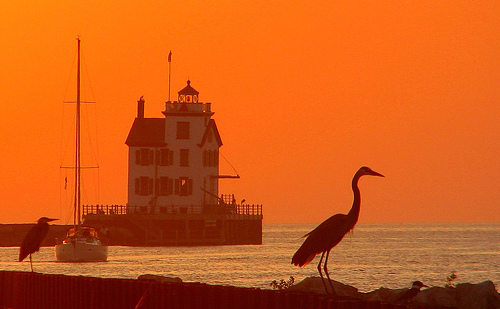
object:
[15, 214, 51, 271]
bird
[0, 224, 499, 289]
water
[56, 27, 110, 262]
boat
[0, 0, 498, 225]
orange sky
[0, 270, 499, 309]
fence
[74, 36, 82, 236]
mast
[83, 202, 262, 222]
fence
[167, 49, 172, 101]
flag pole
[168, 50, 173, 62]
flag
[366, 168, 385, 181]
beak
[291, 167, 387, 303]
bird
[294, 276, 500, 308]
rock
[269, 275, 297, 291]
plants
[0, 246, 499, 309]
seashore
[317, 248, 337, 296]
legs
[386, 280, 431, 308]
bird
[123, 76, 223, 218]
lighthouse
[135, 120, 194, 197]
windows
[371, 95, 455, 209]
ground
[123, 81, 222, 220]
house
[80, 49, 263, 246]
building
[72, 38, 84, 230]
mast sails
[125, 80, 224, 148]
top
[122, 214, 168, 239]
stairs